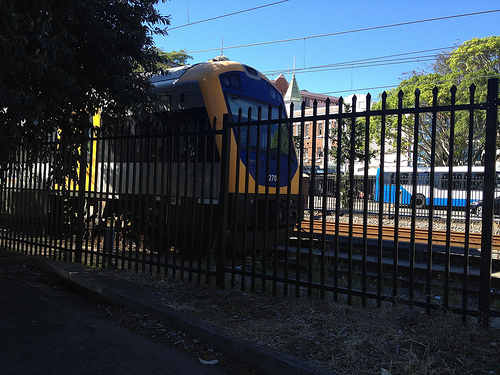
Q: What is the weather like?
A: It is clear.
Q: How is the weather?
A: It is clear.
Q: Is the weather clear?
A: Yes, it is clear.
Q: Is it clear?
A: Yes, it is clear.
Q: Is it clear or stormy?
A: It is clear.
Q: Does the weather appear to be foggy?
A: No, it is clear.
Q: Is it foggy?
A: No, it is clear.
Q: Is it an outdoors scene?
A: Yes, it is outdoors.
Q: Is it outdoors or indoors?
A: It is outdoors.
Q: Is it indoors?
A: No, it is outdoors.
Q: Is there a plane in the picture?
A: No, there are no airplanes.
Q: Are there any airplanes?
A: No, there are no airplanes.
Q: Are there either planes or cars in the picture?
A: No, there are no planes or cars.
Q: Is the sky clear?
A: Yes, the sky is clear.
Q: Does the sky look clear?
A: Yes, the sky is clear.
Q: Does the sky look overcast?
A: No, the sky is clear.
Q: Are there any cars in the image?
A: No, there are no cars.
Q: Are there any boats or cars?
A: No, there are no cars or boats.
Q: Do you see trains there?
A: Yes, there is a train.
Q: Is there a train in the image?
A: Yes, there is a train.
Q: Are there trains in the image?
A: Yes, there is a train.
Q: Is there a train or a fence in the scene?
A: Yes, there is a train.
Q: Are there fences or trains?
A: Yes, there is a train.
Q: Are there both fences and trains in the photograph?
A: Yes, there are both a train and a fence.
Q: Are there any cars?
A: No, there are no cars.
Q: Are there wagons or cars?
A: No, there are no cars or wagons.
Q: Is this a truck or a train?
A: This is a train.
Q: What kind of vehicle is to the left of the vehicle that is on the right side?
A: The vehicle is a train.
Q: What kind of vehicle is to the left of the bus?
A: The vehicle is a train.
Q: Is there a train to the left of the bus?
A: Yes, there is a train to the left of the bus.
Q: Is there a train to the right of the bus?
A: No, the train is to the left of the bus.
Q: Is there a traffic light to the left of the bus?
A: No, there is a train to the left of the bus.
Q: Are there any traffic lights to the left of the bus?
A: No, there is a train to the left of the bus.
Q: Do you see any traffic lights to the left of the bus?
A: No, there is a train to the left of the bus.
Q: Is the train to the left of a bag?
A: No, the train is to the left of a bus.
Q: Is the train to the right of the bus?
A: No, the train is to the left of the bus.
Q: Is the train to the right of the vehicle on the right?
A: No, the train is to the left of the bus.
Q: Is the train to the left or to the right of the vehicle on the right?
A: The train is to the left of the bus.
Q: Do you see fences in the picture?
A: Yes, there is a fence.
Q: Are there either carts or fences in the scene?
A: Yes, there is a fence.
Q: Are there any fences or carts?
A: Yes, there is a fence.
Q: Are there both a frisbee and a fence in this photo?
A: No, there is a fence but no frisbees.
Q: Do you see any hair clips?
A: No, there are no hair clips.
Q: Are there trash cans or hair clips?
A: No, there are no hair clips or trash cans.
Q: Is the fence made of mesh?
A: No, the fence is made of iron.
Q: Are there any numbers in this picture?
A: Yes, there are numbers.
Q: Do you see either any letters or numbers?
A: Yes, there are numbers.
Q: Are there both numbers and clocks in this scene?
A: No, there are numbers but no clocks.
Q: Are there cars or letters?
A: No, there are no cars or letters.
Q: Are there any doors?
A: Yes, there is a door.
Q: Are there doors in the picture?
A: Yes, there is a door.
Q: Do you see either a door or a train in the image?
A: Yes, there is a door.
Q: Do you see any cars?
A: No, there are no cars.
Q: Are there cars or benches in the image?
A: No, there are no cars or benches.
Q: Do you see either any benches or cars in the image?
A: No, there are no cars or benches.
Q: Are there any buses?
A: Yes, there is a bus.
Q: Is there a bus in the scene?
A: Yes, there is a bus.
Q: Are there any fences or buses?
A: Yes, there is a bus.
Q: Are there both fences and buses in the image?
A: Yes, there are both a bus and a fence.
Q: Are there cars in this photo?
A: No, there are no cars.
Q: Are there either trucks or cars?
A: No, there are no cars or trucks.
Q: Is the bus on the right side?
A: Yes, the bus is on the right of the image.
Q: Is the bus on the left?
A: No, the bus is on the right of the image.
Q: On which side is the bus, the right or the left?
A: The bus is on the right of the image.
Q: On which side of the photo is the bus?
A: The bus is on the right of the image.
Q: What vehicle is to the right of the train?
A: The vehicle is a bus.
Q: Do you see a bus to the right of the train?
A: Yes, there is a bus to the right of the train.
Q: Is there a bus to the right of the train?
A: Yes, there is a bus to the right of the train.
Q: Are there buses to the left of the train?
A: No, the bus is to the right of the train.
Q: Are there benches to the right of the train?
A: No, there is a bus to the right of the train.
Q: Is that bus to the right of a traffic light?
A: No, the bus is to the right of a train.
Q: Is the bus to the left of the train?
A: No, the bus is to the right of the train.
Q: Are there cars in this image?
A: No, there are no cars.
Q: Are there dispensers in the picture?
A: No, there are no dispensers.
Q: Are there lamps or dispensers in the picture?
A: No, there are no dispensers or lamps.